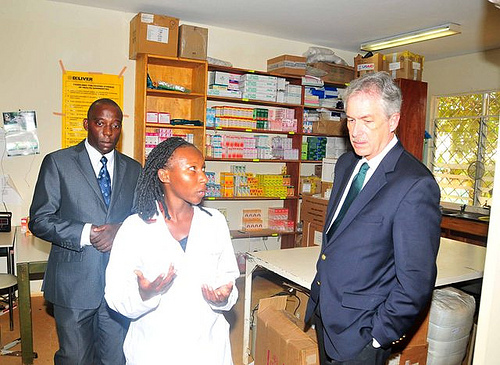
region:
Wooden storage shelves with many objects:
[118, 5, 443, 281]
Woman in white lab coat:
[103, 125, 243, 361]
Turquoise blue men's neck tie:
[314, 151, 374, 250]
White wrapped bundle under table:
[426, 273, 484, 359]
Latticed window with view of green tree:
[422, 89, 497, 223]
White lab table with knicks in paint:
[237, 222, 494, 362]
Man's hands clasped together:
[80, 217, 127, 252]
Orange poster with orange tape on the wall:
[45, 51, 142, 168]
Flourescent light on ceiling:
[345, 15, 470, 55]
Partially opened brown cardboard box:
[236, 285, 343, 361]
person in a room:
[285, 64, 446, 364]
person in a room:
[90, 133, 237, 364]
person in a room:
[16, 90, 156, 364]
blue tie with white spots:
[92, 152, 113, 214]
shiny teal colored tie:
[320, 158, 375, 240]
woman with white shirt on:
[101, 130, 254, 363]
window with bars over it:
[425, 88, 498, 218]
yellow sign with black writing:
[55, 58, 137, 153]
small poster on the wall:
[0, 105, 47, 160]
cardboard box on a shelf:
[122, 8, 179, 61]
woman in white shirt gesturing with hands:
[102, 134, 255, 364]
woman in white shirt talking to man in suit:
[102, 61, 446, 361]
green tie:
[325, 159, 372, 241]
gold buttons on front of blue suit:
[310, 251, 331, 292]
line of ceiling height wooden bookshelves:
[135, 61, 361, 263]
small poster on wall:
[2, 103, 44, 162]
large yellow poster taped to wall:
[52, 61, 129, 149]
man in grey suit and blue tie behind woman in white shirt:
[22, 93, 157, 360]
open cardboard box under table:
[253, 289, 318, 364]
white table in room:
[234, 233, 484, 363]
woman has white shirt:
[103, 201, 273, 336]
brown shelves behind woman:
[136, 71, 228, 181]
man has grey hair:
[313, 74, 398, 127]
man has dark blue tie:
[325, 128, 397, 235]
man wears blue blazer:
[301, 138, 414, 340]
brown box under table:
[264, 303, 332, 363]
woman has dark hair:
[124, 149, 219, 205]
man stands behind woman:
[40, 106, 137, 350]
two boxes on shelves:
[124, 17, 206, 64]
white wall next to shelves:
[21, 18, 116, 63]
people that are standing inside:
[30, 48, 472, 360]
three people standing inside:
[22, 26, 462, 363]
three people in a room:
[40, 33, 457, 360]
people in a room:
[26, 22, 483, 362]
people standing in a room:
[29, 76, 499, 321]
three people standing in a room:
[24, 70, 467, 362]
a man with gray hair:
[287, 51, 446, 356]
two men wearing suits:
[26, 54, 437, 360]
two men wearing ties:
[18, 43, 482, 324]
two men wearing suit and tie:
[54, 56, 489, 362]